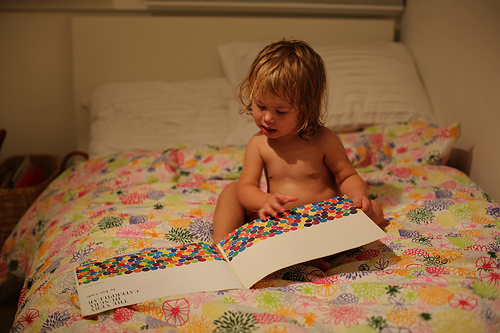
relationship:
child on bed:
[205, 31, 389, 257] [21, 9, 498, 331]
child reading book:
[205, 31, 389, 257] [74, 193, 385, 318]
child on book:
[205, 31, 389, 257] [74, 193, 385, 318]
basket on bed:
[0, 150, 62, 256] [21, 9, 498, 331]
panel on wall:
[73, 13, 400, 158] [1, 0, 497, 190]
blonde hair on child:
[237, 35, 329, 130] [206, 34, 384, 228]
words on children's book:
[82, 281, 147, 316] [74, 192, 386, 318]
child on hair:
[205, 31, 389, 257] [242, 37, 338, 127]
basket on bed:
[0, 150, 62, 241] [62, 146, 292, 291]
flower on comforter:
[162, 297, 199, 325] [174, 295, 303, 331]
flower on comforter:
[215, 311, 255, 331] [9, 122, 499, 322]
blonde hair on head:
[237, 36, 330, 141] [257, 34, 327, 138]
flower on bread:
[92, 211, 124, 235] [14, 120, 491, 328]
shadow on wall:
[445, 143, 477, 178] [386, 2, 498, 206]